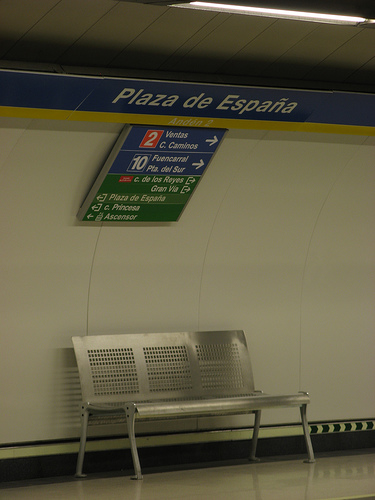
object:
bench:
[71, 328, 319, 481]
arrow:
[204, 135, 220, 148]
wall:
[0, 68, 372, 482]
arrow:
[190, 159, 207, 172]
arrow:
[84, 212, 96, 222]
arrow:
[96, 193, 103, 203]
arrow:
[181, 186, 193, 194]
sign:
[76, 122, 230, 225]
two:
[144, 131, 157, 147]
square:
[138, 129, 166, 148]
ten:
[132, 155, 148, 171]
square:
[127, 151, 154, 174]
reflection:
[309, 467, 373, 477]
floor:
[0, 447, 373, 500]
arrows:
[308, 420, 373, 434]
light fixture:
[170, 0, 372, 27]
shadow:
[52, 346, 140, 423]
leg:
[76, 411, 87, 479]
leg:
[123, 403, 143, 479]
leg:
[249, 409, 264, 462]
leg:
[299, 404, 315, 464]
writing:
[159, 130, 202, 151]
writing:
[133, 174, 186, 193]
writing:
[107, 193, 168, 205]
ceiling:
[1, 2, 374, 91]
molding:
[1, 419, 374, 483]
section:
[142, 345, 198, 394]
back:
[72, 329, 256, 402]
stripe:
[0, 429, 374, 483]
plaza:
[113, 87, 179, 110]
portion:
[81, 175, 200, 224]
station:
[0, 0, 372, 499]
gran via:
[150, 183, 179, 195]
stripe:
[0, 70, 374, 126]